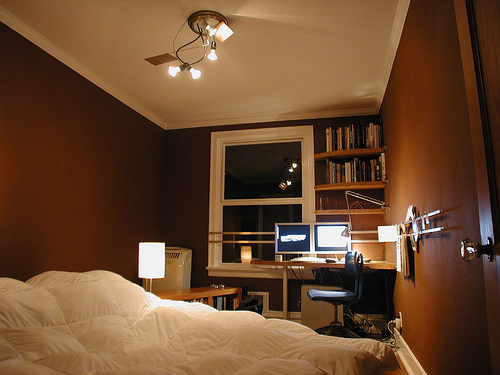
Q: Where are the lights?
A: On the ceiling.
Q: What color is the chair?
A: Blue.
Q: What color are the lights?
A: Yellow.